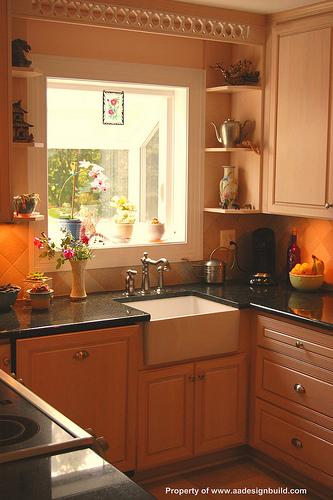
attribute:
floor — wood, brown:
[226, 473, 265, 486]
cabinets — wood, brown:
[71, 367, 114, 413]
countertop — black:
[263, 293, 315, 321]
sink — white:
[148, 310, 223, 357]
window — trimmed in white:
[49, 72, 201, 256]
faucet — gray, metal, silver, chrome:
[115, 258, 178, 287]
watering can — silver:
[206, 110, 262, 144]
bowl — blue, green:
[290, 280, 326, 295]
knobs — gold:
[278, 373, 314, 403]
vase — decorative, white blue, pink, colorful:
[210, 160, 244, 209]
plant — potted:
[115, 199, 138, 226]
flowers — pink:
[52, 231, 99, 258]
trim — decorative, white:
[159, 17, 250, 36]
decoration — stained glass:
[95, 83, 157, 135]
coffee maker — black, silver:
[250, 225, 281, 272]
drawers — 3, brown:
[256, 321, 327, 472]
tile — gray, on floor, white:
[182, 477, 210, 498]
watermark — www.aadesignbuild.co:
[147, 481, 319, 498]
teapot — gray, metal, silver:
[208, 121, 255, 150]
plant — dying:
[13, 188, 38, 211]